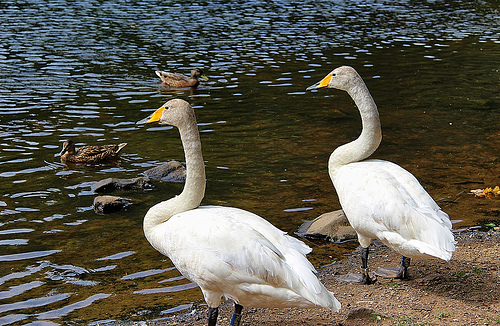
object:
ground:
[342, 252, 499, 326]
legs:
[207, 301, 245, 326]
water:
[107, 15, 468, 166]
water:
[0, 0, 497, 324]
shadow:
[406, 260, 500, 308]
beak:
[136, 107, 166, 125]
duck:
[155, 67, 209, 87]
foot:
[337, 242, 378, 285]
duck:
[58, 138, 128, 164]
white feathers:
[173, 215, 290, 287]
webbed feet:
[333, 245, 379, 285]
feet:
[336, 247, 412, 285]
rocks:
[91, 176, 156, 214]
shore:
[315, 260, 497, 326]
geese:
[133, 63, 457, 326]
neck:
[175, 128, 206, 195]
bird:
[134, 97, 343, 326]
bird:
[305, 65, 456, 286]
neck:
[325, 87, 383, 163]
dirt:
[344, 301, 382, 323]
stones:
[36, 16, 106, 109]